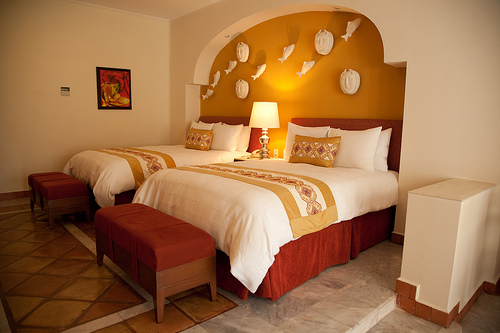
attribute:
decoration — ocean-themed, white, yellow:
[192, 8, 409, 118]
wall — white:
[5, 6, 177, 182]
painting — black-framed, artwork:
[94, 65, 136, 112]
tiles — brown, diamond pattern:
[3, 194, 136, 332]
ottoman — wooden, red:
[19, 171, 213, 314]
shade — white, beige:
[248, 103, 285, 129]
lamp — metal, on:
[249, 99, 280, 159]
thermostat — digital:
[57, 85, 77, 101]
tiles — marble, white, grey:
[247, 254, 412, 331]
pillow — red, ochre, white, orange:
[282, 120, 386, 176]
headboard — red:
[195, 112, 401, 169]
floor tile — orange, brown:
[10, 191, 208, 332]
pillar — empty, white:
[405, 177, 490, 323]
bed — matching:
[69, 115, 393, 262]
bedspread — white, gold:
[91, 133, 374, 232]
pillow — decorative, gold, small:
[287, 136, 339, 167]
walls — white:
[3, 1, 495, 245]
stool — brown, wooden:
[100, 255, 221, 319]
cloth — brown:
[97, 195, 209, 269]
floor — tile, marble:
[21, 229, 422, 332]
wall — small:
[396, 164, 445, 244]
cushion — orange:
[34, 170, 190, 274]